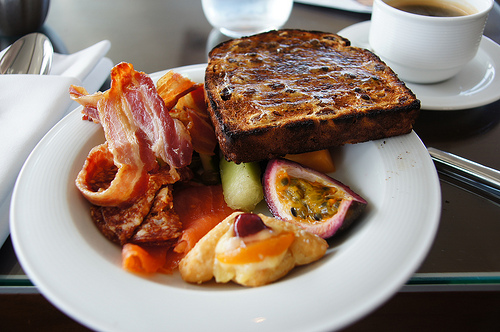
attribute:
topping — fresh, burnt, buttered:
[203, 30, 418, 162]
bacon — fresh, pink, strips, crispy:
[69, 60, 232, 208]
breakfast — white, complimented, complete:
[15, 1, 499, 330]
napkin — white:
[5, 33, 111, 253]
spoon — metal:
[7, 30, 52, 77]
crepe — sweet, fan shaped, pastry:
[183, 210, 329, 288]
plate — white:
[8, 57, 445, 331]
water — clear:
[199, 0, 293, 40]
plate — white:
[335, 17, 498, 112]